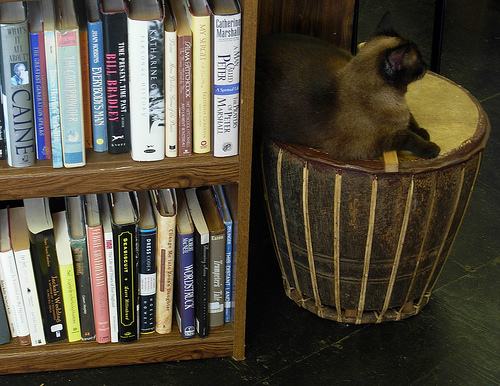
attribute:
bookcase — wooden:
[7, 17, 285, 364]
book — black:
[108, 190, 140, 342]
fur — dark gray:
[279, 63, 311, 103]